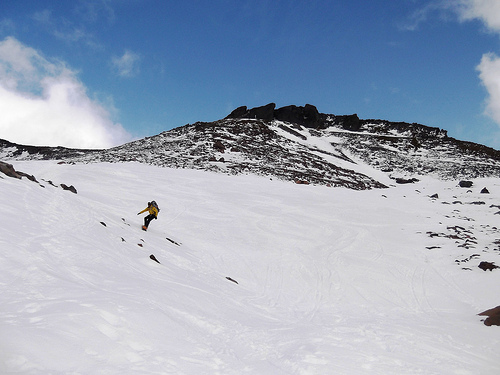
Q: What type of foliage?
A: Plants.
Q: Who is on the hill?
A: Skier.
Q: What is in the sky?
A: Clouds.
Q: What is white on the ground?
A: Snow.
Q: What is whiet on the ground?
A: Snow.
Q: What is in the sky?
A: Clouds.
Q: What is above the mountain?
A: Sky.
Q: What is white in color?
A: Snow.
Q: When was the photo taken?
A: During the daytime.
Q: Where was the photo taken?
A: On a mountain.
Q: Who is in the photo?
A: A person.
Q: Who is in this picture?
A: Snowboarder.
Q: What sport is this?
A: Snowboarding.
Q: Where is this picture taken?
A: Mountain.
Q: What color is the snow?
A: White.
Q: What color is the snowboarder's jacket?
A: Yellow.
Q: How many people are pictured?
A: 1.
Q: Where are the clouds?
A: In sky.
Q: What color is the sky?
A: Blue.